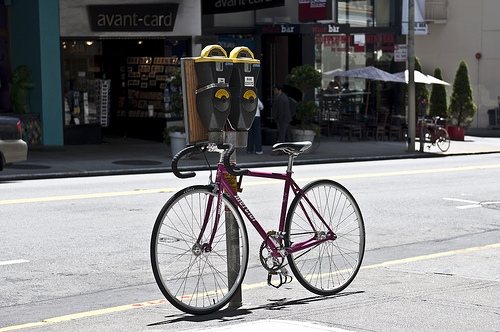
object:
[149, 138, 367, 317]
bike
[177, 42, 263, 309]
parking meter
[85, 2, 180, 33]
sign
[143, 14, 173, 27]
lettering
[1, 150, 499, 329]
street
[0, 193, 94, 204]
line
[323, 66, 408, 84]
umbrella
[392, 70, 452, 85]
umbrella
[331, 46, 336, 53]
lettering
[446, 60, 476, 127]
tree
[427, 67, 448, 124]
tree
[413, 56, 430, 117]
tree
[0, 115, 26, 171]
vehicle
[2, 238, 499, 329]
sidewalk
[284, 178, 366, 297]
tire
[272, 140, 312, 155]
seat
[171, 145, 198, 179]
handle bars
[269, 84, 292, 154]
person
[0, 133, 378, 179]
sidewalk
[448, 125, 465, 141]
planter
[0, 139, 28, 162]
bumper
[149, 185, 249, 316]
wheel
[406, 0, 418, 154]
pole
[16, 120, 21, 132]
tail light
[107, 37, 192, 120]
window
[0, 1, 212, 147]
building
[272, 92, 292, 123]
suit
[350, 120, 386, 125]
table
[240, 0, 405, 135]
bar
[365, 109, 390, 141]
chair